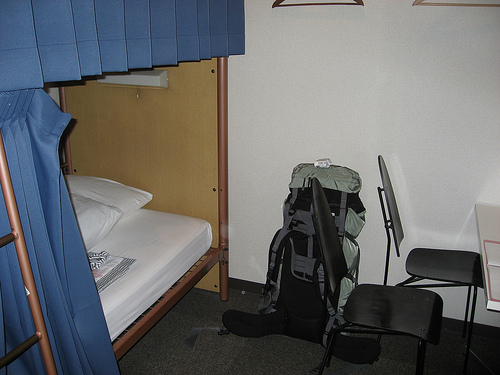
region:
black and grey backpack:
[256, 157, 366, 345]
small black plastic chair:
[304, 191, 454, 362]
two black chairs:
[295, 151, 481, 370]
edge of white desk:
[461, 182, 498, 315]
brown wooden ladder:
[0, 155, 65, 372]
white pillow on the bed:
[39, 173, 139, 235]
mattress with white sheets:
[60, 210, 229, 329]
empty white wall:
[264, 28, 448, 136]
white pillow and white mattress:
[50, 161, 160, 265]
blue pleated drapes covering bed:
[1, 0, 231, 94]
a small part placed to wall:
[368, 160, 417, 260]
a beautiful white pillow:
[58, 127, 136, 250]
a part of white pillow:
[75, 165, 159, 230]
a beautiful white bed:
[87, 223, 222, 293]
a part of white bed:
[138, 204, 228, 330]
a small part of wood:
[124, 65, 251, 307]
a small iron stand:
[9, 204, 86, 366]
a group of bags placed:
[258, 135, 393, 354]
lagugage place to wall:
[258, 122, 402, 369]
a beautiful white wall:
[229, 0, 499, 254]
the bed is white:
[110, 198, 198, 325]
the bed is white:
[125, 212, 257, 360]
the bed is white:
[161, 251, 243, 368]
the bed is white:
[127, 135, 254, 322]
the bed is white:
[65, 147, 236, 351]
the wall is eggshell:
[226, 0, 499, 330]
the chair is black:
[299, 175, 446, 373]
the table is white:
[469, 191, 499, 321]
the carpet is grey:
[93, 273, 499, 373]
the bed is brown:
[0, 49, 242, 374]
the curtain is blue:
[0, 85, 124, 374]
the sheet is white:
[82, 203, 213, 347]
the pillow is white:
[56, 166, 156, 253]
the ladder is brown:
[0, 124, 62, 374]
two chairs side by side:
[298, 147, 491, 374]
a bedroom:
[11, 3, 497, 370]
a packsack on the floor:
[252, 150, 368, 347]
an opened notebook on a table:
[483, 234, 498, 304]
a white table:
[471, 196, 499, 240]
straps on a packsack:
[261, 192, 342, 304]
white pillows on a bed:
[66, 162, 153, 231]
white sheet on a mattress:
[123, 205, 220, 288]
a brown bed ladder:
[0, 154, 69, 374]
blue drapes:
[1, 122, 117, 372]